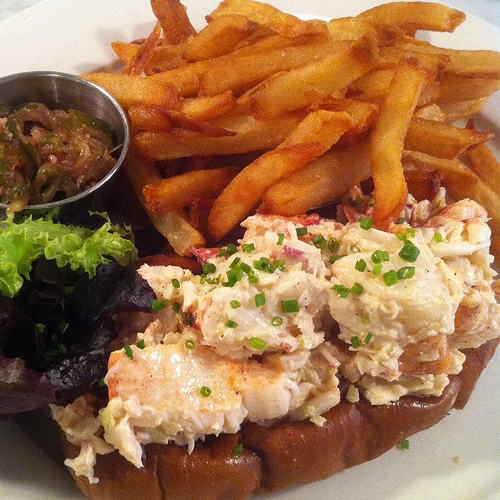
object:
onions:
[351, 259, 369, 276]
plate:
[0, 0, 500, 499]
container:
[0, 68, 134, 224]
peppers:
[60, 139, 92, 176]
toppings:
[216, 259, 330, 308]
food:
[248, 333, 266, 353]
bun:
[59, 369, 464, 499]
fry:
[142, 167, 239, 216]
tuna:
[198, 240, 330, 358]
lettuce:
[0, 215, 137, 303]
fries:
[367, 55, 430, 229]